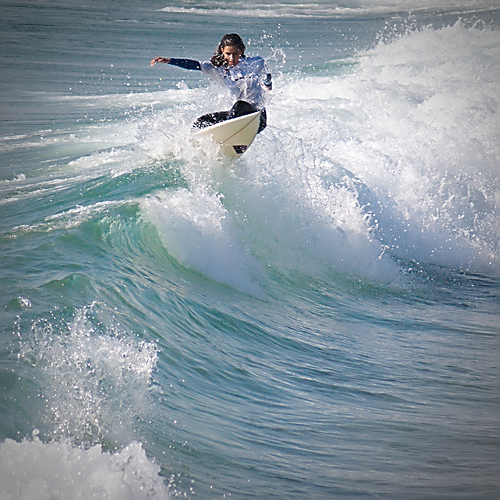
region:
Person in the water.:
[168, 20, 265, 160]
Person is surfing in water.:
[188, 20, 295, 155]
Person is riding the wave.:
[193, 36, 299, 151]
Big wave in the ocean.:
[278, 44, 450, 194]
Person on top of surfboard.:
[181, 85, 297, 182]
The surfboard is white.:
[197, 114, 276, 171]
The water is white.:
[373, 68, 448, 191]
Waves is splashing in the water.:
[42, 328, 173, 480]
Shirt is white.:
[211, 59, 271, 89]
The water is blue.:
[93, 229, 455, 416]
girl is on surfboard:
[166, 37, 276, 142]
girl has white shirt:
[205, 60, 270, 120]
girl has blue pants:
[202, 102, 262, 138]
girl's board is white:
[195, 113, 256, 155]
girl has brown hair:
[217, 17, 239, 57]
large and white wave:
[282, 51, 497, 243]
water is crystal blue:
[307, 283, 478, 395]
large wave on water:
[195, 67, 497, 302]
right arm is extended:
[168, 47, 220, 104]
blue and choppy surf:
[22, 13, 389, 184]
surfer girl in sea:
[145, 26, 272, 160]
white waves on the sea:
[1, 20, 496, 497]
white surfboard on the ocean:
[173, 108, 259, 170]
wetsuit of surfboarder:
[193, 56, 267, 141]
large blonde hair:
[213, 33, 244, 73]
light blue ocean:
[6, 3, 499, 498]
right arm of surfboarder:
[151, 53, 219, 79]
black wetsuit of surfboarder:
[189, 100, 265, 160]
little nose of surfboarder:
[228, 53, 235, 63]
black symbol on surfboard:
[233, 142, 248, 156]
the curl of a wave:
[21, 192, 488, 479]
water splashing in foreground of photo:
[0, 287, 181, 496]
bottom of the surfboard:
[186, 112, 297, 166]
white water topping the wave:
[268, 3, 497, 305]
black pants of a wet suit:
[188, 103, 265, 148]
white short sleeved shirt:
[206, 55, 273, 106]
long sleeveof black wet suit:
[163, 41, 201, 73]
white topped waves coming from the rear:
[158, 1, 473, 38]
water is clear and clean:
[0, 130, 180, 335]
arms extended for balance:
[146, 42, 315, 92]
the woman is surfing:
[129, 3, 306, 188]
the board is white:
[171, 95, 274, 191]